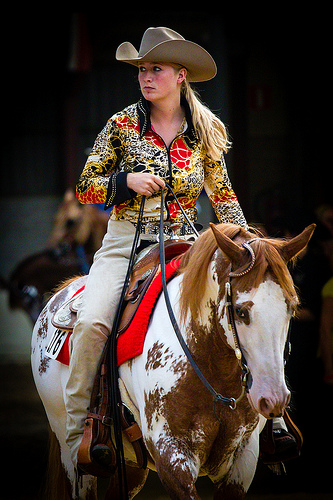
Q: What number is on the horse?
A: 176.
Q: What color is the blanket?
A: Red.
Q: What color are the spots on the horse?
A: Brown.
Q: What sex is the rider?
A: Female.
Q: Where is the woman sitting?
A: In the saddle.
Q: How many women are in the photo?
A: 1.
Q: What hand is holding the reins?
A: Right.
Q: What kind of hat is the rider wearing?
A: Cowboy hat.